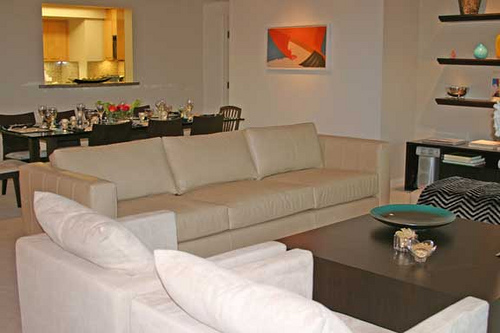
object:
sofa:
[18, 121, 395, 259]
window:
[38, 5, 138, 86]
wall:
[1, 2, 208, 118]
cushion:
[258, 167, 380, 211]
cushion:
[174, 178, 314, 230]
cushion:
[114, 193, 232, 244]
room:
[0, 0, 499, 332]